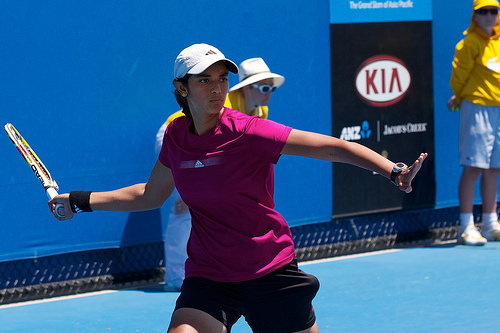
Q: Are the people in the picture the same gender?
A: No, they are both male and female.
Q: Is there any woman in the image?
A: Yes, there is a woman.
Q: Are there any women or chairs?
A: Yes, there is a woman.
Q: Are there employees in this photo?
A: No, there are no employees.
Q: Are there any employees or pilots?
A: No, there are no employees or pilots.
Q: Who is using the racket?
A: The woman is using the racket.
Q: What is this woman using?
A: The woman is using a racket.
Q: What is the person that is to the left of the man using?
A: The woman is using a racket.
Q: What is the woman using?
A: The woman is using a racket.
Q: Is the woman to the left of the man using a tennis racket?
A: Yes, the woman is using a tennis racket.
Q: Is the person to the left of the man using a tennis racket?
A: Yes, the woman is using a tennis racket.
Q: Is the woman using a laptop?
A: No, the woman is using a tennis racket.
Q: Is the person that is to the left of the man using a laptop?
A: No, the woman is using a tennis racket.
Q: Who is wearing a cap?
A: The woman is wearing a cap.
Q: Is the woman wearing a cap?
A: Yes, the woman is wearing a cap.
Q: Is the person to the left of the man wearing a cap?
A: Yes, the woman is wearing a cap.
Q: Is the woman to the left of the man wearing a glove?
A: No, the woman is wearing a cap.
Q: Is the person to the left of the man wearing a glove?
A: No, the woman is wearing a cap.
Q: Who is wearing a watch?
A: The woman is wearing a watch.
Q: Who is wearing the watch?
A: The woman is wearing a watch.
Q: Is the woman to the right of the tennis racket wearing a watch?
A: Yes, the woman is wearing a watch.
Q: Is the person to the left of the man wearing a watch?
A: Yes, the woman is wearing a watch.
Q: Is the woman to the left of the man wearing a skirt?
A: No, the woman is wearing a watch.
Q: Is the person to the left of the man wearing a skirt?
A: No, the woman is wearing a watch.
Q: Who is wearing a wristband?
A: The woman is wearing a wristband.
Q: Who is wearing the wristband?
A: The woman is wearing a wristband.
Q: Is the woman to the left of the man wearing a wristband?
A: Yes, the woman is wearing a wristband.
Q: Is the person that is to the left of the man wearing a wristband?
A: Yes, the woman is wearing a wristband.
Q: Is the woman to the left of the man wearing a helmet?
A: No, the woman is wearing a wristband.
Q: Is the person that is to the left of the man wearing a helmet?
A: No, the woman is wearing a wristband.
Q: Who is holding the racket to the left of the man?
A: The woman is holding the racket.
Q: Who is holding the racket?
A: The woman is holding the racket.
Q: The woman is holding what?
A: The woman is holding the tennis racket.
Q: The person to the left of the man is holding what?
A: The woman is holding the tennis racket.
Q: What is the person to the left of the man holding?
A: The woman is holding the tennis racket.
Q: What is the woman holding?
A: The woman is holding the tennis racket.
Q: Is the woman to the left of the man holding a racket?
A: Yes, the woman is holding a racket.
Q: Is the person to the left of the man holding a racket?
A: Yes, the woman is holding a racket.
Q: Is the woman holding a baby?
A: No, the woman is holding a racket.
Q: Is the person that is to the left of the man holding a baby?
A: No, the woman is holding a racket.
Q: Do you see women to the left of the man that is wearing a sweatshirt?
A: Yes, there is a woman to the left of the man.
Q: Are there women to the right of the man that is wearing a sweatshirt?
A: No, the woman is to the left of the man.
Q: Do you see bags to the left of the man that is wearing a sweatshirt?
A: No, there is a woman to the left of the man.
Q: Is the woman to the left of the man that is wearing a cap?
A: Yes, the woman is to the left of the man.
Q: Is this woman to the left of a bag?
A: No, the woman is to the left of the man.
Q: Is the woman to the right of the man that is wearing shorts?
A: No, the woman is to the left of the man.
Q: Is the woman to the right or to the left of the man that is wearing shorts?
A: The woman is to the left of the man.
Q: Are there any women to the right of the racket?
A: Yes, there is a woman to the right of the racket.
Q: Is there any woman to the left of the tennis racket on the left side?
A: No, the woman is to the right of the racket.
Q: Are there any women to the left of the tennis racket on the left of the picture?
A: No, the woman is to the right of the racket.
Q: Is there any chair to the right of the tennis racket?
A: No, there is a woman to the right of the tennis racket.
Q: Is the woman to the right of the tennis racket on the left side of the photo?
A: Yes, the woman is to the right of the racket.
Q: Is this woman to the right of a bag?
A: No, the woman is to the right of the racket.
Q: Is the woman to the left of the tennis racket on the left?
A: No, the woman is to the right of the tennis racket.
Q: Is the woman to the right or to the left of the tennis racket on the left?
A: The woman is to the right of the racket.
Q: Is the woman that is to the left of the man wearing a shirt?
A: Yes, the woman is wearing a shirt.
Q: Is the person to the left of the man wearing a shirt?
A: Yes, the woman is wearing a shirt.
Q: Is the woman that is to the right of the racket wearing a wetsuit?
A: No, the woman is wearing a shirt.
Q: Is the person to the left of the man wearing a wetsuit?
A: No, the woman is wearing a shirt.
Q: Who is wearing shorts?
A: The woman is wearing shorts.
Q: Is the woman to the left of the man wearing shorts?
A: Yes, the woman is wearing shorts.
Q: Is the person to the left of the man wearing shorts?
A: Yes, the woman is wearing shorts.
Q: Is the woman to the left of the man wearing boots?
A: No, the woman is wearing shorts.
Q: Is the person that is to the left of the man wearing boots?
A: No, the woman is wearing shorts.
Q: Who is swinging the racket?
A: The woman is swinging the racket.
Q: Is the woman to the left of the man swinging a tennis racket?
A: Yes, the woman is swinging a tennis racket.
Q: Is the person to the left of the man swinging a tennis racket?
A: Yes, the woman is swinging a tennis racket.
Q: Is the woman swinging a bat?
A: No, the woman is swinging a tennis racket.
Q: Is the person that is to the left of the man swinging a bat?
A: No, the woman is swinging a tennis racket.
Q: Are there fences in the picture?
A: No, there are no fences.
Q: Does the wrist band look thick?
A: Yes, the wrist band is thick.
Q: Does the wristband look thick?
A: Yes, the wristband is thick.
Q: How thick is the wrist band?
A: The wrist band is thick.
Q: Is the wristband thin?
A: No, the wristband is thick.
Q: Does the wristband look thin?
A: No, the wristband is thick.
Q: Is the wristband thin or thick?
A: The wristband is thick.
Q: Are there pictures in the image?
A: No, there are no pictures.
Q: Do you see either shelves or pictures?
A: No, there are no pictures or shelves.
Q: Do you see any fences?
A: No, there are no fences.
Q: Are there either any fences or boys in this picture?
A: No, there are no fences or boys.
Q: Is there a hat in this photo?
A: Yes, there is a hat.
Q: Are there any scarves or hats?
A: Yes, there is a hat.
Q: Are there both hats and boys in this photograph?
A: No, there is a hat but no boys.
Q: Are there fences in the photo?
A: No, there are no fences.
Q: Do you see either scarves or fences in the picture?
A: No, there are no fences or scarves.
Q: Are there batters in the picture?
A: No, there are no batters.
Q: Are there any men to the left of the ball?
A: Yes, there is a man to the left of the ball.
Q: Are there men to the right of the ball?
A: No, the man is to the left of the ball.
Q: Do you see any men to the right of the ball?
A: No, the man is to the left of the ball.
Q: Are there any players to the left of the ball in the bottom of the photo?
A: No, there is a man to the left of the ball.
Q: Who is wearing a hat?
A: The man is wearing a hat.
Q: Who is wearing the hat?
A: The man is wearing a hat.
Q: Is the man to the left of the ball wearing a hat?
A: Yes, the man is wearing a hat.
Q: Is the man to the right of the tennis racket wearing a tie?
A: No, the man is wearing a hat.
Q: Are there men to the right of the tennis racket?
A: Yes, there is a man to the right of the tennis racket.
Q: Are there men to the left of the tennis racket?
A: No, the man is to the right of the tennis racket.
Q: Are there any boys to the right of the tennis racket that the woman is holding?
A: No, there is a man to the right of the tennis racket.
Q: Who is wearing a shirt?
A: The man is wearing a shirt.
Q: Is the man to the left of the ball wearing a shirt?
A: Yes, the man is wearing a shirt.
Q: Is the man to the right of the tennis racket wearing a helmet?
A: No, the man is wearing a shirt.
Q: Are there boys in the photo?
A: No, there are no boys.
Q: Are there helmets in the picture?
A: No, there are no helmets.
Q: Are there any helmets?
A: No, there are no helmets.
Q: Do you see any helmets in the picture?
A: No, there are no helmets.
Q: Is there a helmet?
A: No, there are no helmets.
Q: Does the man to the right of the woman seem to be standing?
A: Yes, the man is standing.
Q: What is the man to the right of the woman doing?
A: The man is standing.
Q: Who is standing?
A: The man is standing.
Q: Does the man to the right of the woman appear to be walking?
A: No, the man is standing.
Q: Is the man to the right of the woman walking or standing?
A: The man is standing.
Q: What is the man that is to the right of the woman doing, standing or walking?
A: The man is standing.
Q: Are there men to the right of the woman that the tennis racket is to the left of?
A: Yes, there is a man to the right of the woman.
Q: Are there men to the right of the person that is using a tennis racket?
A: Yes, there is a man to the right of the woman.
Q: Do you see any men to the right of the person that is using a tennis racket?
A: Yes, there is a man to the right of the woman.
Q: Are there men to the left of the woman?
A: No, the man is to the right of the woman.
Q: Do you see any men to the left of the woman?
A: No, the man is to the right of the woman.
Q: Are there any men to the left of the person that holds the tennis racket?
A: No, the man is to the right of the woman.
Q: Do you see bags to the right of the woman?
A: No, there is a man to the right of the woman.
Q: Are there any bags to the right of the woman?
A: No, there is a man to the right of the woman.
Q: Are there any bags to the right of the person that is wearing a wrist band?
A: No, there is a man to the right of the woman.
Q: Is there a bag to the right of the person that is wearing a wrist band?
A: No, there is a man to the right of the woman.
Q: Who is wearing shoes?
A: The man is wearing shoes.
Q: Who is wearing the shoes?
A: The man is wearing shoes.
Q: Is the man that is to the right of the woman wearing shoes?
A: Yes, the man is wearing shoes.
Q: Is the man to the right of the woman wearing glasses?
A: No, the man is wearing shoes.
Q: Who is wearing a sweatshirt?
A: The man is wearing a sweatshirt.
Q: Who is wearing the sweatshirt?
A: The man is wearing a sweatshirt.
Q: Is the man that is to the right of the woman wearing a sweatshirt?
A: Yes, the man is wearing a sweatshirt.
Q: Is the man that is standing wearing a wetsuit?
A: No, the man is wearing a sweatshirt.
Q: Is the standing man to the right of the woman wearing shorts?
A: Yes, the man is wearing shorts.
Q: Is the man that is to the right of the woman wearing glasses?
A: No, the man is wearing shorts.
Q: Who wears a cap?
A: The man wears a cap.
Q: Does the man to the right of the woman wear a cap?
A: Yes, the man wears a cap.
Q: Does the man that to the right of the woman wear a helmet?
A: No, the man wears a cap.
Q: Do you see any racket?
A: Yes, there is a racket.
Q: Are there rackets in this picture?
A: Yes, there is a racket.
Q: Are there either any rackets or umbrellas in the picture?
A: Yes, there is a racket.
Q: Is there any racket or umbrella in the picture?
A: Yes, there is a racket.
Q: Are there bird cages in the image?
A: No, there are no bird cages.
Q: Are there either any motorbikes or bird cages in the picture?
A: No, there are no bird cages or motorbikes.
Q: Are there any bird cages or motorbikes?
A: No, there are no bird cages or motorbikes.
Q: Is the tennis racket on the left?
A: Yes, the tennis racket is on the left of the image.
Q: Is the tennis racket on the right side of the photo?
A: No, the tennis racket is on the left of the image.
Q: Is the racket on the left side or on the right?
A: The racket is on the left of the image.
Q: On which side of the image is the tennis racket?
A: The tennis racket is on the left of the image.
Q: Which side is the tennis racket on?
A: The tennis racket is on the left of the image.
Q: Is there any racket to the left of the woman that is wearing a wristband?
A: Yes, there is a racket to the left of the woman.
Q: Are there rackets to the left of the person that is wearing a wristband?
A: Yes, there is a racket to the left of the woman.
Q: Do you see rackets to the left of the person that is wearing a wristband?
A: Yes, there is a racket to the left of the woman.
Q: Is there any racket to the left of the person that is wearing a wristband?
A: Yes, there is a racket to the left of the woman.